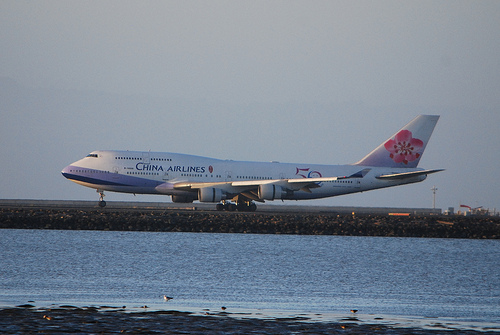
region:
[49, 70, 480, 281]
the plane has a big flower on the tail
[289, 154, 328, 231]
the plane has a 50 on the side of it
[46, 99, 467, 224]
the plane has writing on the side of it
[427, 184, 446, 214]
a control tower is in the background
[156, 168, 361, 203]
the plane has a large wing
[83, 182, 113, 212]
the landing gear is down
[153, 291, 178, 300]
a bird is in the water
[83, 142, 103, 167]
the cockpit of the plane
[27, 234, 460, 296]
the water is blue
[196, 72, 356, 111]
the sky is rather grey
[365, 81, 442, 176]
pink and red blossom on tail of plane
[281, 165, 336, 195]
wing covering the number on the plane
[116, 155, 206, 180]
company name in blue capital letters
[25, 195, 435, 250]
plane on landing area by water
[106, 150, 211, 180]
two levels of passenger windows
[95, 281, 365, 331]
birds along the edge of water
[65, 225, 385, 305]
ripples across water surface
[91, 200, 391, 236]
rocks on side of landing area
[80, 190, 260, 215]
wheels below airplane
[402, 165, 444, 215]
airport tower in distance behind plane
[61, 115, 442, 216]
Airplane flying over a body of water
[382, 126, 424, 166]
Red logo on the tail of the airplane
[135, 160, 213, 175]
Airline logo on the left side of the airplane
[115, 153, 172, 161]
Windows on the left side of the airplane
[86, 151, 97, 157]
Cockpit window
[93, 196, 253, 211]
Wheels of the airplane used for landing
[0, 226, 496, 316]
Body of water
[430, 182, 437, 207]
Water plant that's distant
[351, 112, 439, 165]
Tail of the airplane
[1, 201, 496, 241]
Cities and forestland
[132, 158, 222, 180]
China Airline passenger airplane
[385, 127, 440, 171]
hot pink flower on tail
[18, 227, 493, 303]
calm blue water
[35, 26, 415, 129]
clear cloudless blue sky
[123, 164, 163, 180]
small windows of airplane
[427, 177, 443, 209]
air traffic control tower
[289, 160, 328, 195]
number 50 on side of plane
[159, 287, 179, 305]
seagull sitting in water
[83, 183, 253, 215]
wheels on runway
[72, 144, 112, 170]
window of plane's cockpit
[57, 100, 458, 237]
Airplane is on the ground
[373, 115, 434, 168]
Airplanes tail has a flower on it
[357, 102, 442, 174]
The flower is bright pink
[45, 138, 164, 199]
Front of the airplane has a blue stripe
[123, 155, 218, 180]
Side view of Airplane says "China Airlines"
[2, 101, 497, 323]
Airplane is in front of a body of water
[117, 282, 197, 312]
A small bird is in the water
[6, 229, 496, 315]
Body of water is blue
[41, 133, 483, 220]
Airplanes main color is white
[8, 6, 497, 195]
The sky is cloudy